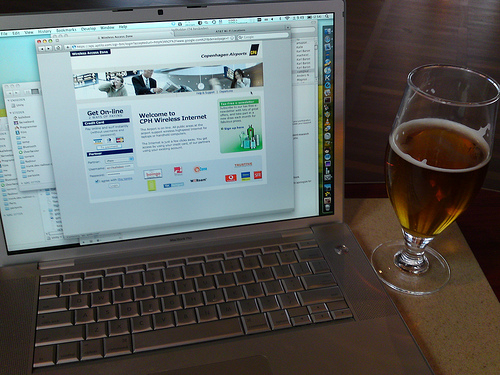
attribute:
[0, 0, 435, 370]
laptop — GREY, ON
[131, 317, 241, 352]
bar key — space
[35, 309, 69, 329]
lock key — caps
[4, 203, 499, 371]
desk — WOODEN, Brown 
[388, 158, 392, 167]
marking — Red 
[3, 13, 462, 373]
laptop — Open 